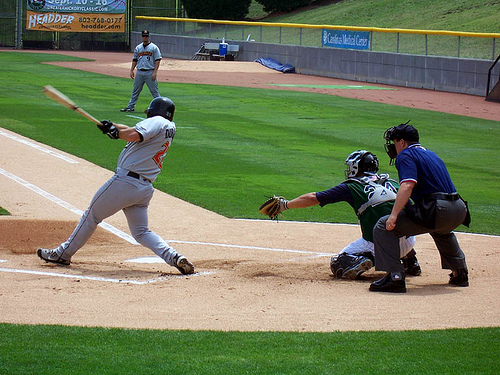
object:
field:
[0, 46, 500, 373]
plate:
[127, 254, 167, 266]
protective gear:
[342, 147, 392, 217]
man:
[257, 148, 427, 282]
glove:
[256, 193, 288, 224]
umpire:
[368, 119, 468, 294]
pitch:
[0, 127, 500, 333]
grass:
[0, 49, 500, 238]